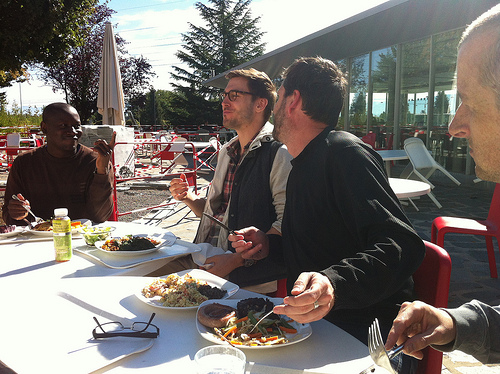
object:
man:
[168, 68, 292, 277]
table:
[373, 150, 411, 162]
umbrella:
[97, 22, 126, 126]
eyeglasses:
[218, 89, 258, 103]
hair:
[280, 55, 348, 126]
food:
[32, 221, 81, 231]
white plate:
[28, 219, 83, 236]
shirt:
[428, 298, 500, 365]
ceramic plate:
[97, 237, 164, 262]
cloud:
[129, 6, 166, 43]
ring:
[313, 301, 319, 308]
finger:
[403, 325, 440, 356]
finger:
[290, 272, 312, 295]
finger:
[242, 243, 263, 259]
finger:
[384, 310, 417, 351]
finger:
[179, 172, 186, 183]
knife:
[202, 212, 262, 252]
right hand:
[228, 225, 270, 260]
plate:
[133, 269, 239, 310]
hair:
[224, 68, 280, 122]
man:
[2, 102, 117, 226]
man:
[382, 1, 500, 362]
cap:
[54, 207, 69, 216]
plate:
[195, 298, 312, 350]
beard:
[223, 108, 254, 130]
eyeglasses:
[91, 313, 160, 340]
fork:
[367, 318, 405, 374]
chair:
[400, 138, 462, 213]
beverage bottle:
[50, 206, 72, 261]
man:
[226, 56, 424, 374]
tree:
[161, 0, 266, 128]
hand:
[385, 300, 454, 358]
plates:
[93, 237, 166, 256]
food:
[198, 298, 296, 346]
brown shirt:
[1, 143, 118, 226]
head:
[272, 56, 348, 143]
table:
[0, 221, 393, 374]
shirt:
[268, 126, 426, 309]